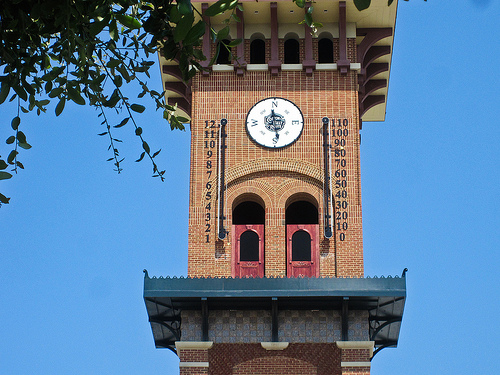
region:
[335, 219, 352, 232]
The numbers are black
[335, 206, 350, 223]
The numbers are black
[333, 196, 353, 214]
The numbers are black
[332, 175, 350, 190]
The numbers are black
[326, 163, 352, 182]
The numbers are black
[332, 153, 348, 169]
The numbers are black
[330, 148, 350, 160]
The numbers are black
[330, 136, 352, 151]
The numbers are black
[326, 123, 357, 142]
The numbers are black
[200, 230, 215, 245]
The number is black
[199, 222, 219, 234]
The number is black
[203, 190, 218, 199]
The number is black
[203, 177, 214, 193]
The number is black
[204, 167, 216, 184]
The number is black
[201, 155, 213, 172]
The number is black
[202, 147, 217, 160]
The number is black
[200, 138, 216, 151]
The number is black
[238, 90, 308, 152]
clock on the side of the tower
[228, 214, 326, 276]
two red doors on the side of the building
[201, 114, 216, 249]
numbers in a vertical line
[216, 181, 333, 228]
archways over the door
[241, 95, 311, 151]
black and white compass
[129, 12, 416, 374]
tower is made of brick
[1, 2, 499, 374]
no clouds in the bright blue sky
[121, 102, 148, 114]
green leaf on the branch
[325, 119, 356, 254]
black numbers on the brick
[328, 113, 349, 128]
The number is black.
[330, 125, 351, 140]
The number is black.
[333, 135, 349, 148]
The number is black.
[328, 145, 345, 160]
The number is black.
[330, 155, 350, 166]
The number is black.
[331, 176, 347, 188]
The number is black.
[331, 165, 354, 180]
The number is black.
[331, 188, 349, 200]
The number is black.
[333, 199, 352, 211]
The number is black.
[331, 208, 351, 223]
The number is black.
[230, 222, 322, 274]
two red doors with arched windows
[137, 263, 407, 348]
a platform wraps around the compass tower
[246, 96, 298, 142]
a compass with a white face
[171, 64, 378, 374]
red brick tower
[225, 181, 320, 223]
arches ovcer the red doors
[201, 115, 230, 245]
a slide indicator of the month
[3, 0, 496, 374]
a clear blue sky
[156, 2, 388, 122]
eaves above the compass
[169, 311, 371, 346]
white textured wall area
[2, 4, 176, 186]
the deep green leaves of a nearby tree branch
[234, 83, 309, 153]
compass on top of tower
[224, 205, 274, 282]
red door on the towers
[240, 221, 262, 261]
a window on a building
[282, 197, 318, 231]
a window on a building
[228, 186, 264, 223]
a window on a building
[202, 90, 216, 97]
a brick in a wall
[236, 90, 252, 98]
a brick in a wall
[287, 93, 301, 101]
a brick in a wall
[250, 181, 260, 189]
a brick in a wall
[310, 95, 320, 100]
a brick in a wall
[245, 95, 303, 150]
A large compass on a brick structure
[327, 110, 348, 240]
A set of numbers on the right side of the building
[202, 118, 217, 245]
A set of numbers on the left side of the building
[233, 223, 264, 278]
Left red door on brick building